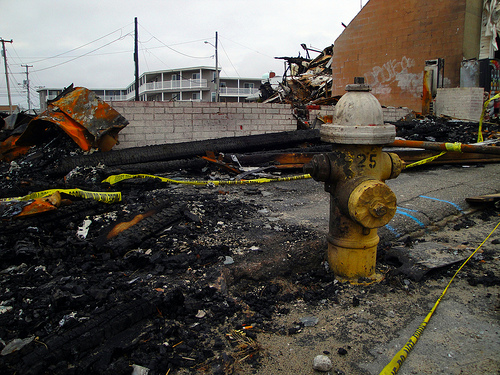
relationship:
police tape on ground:
[99, 172, 312, 185] [14, 114, 497, 363]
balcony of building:
[91, 77, 210, 94] [35, 61, 265, 109]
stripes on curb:
[383, 189, 470, 239] [386, 164, 499, 245]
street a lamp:
[1, 134, 491, 374] [202, 36, 215, 50]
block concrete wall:
[434, 85, 487, 125] [102, 93, 298, 149]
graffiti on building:
[363, 52, 455, 101] [327, 0, 484, 120]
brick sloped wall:
[325, 2, 464, 119] [102, 93, 298, 149]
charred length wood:
[395, 110, 465, 146] [392, 142, 499, 167]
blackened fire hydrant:
[309, 143, 354, 235] [312, 79, 413, 279]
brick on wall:
[325, 2, 464, 119] [102, 93, 298, 149]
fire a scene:
[9, 136, 276, 361] [1, 23, 498, 371]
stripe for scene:
[476, 87, 499, 144] [1, 23, 498, 371]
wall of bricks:
[102, 93, 298, 149] [330, 2, 466, 114]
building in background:
[35, 61, 265, 109] [0, 4, 365, 108]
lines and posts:
[19, 25, 139, 73] [0, 32, 42, 110]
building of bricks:
[35, 61, 265, 109] [330, 2, 466, 114]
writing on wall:
[359, 56, 462, 113] [102, 93, 298, 149]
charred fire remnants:
[395, 110, 465, 146] [58, 91, 124, 142]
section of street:
[274, 264, 496, 359] [1, 134, 491, 374]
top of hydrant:
[343, 75, 370, 93] [312, 79, 413, 279]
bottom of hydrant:
[315, 241, 389, 279] [312, 79, 413, 279]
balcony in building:
[91, 77, 210, 94] [35, 61, 265, 109]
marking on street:
[419, 194, 462, 220] [1, 134, 491, 374]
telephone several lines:
[3, 38, 20, 99] [19, 25, 139, 73]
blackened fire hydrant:
[301, 140, 355, 239] [312, 79, 413, 279]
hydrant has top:
[312, 79, 413, 279] [343, 75, 370, 93]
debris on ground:
[198, 143, 314, 168] [14, 114, 497, 363]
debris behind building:
[245, 23, 348, 100] [35, 61, 265, 109]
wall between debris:
[102, 93, 298, 149] [198, 143, 314, 168]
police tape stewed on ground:
[381, 221, 498, 373] [27, 243, 296, 368]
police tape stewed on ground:
[3, 186, 125, 211] [27, 243, 296, 368]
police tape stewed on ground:
[102, 171, 314, 184] [27, 243, 296, 368]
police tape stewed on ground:
[404, 142, 460, 167] [27, 243, 296, 368]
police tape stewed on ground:
[478, 93, 498, 140] [27, 243, 296, 368]